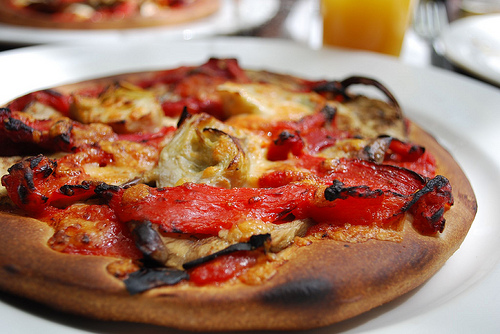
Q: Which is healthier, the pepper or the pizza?
A: The pepper is healthier than the pizza.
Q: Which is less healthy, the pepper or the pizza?
A: The pizza is less healthy than the pepper.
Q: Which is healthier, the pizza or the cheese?
A: The cheese is healthier than the pizza.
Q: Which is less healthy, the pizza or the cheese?
A: The pizza is less healthy than the cheese.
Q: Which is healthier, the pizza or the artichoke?
A: The artichoke is healthier than the pizza.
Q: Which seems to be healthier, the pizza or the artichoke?
A: The artichoke is healthier than the pizza.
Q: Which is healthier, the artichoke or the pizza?
A: The artichoke is healthier than the pizza.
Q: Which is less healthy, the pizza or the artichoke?
A: The pizza is less healthy than the artichoke.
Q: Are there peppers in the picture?
A: Yes, there is a pepper.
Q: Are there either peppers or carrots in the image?
A: Yes, there is a pepper.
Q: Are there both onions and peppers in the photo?
A: No, there is a pepper but no onions.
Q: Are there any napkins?
A: No, there are no napkins.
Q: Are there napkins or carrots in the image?
A: No, there are no napkins or carrots.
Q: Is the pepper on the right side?
A: Yes, the pepper is on the right of the image.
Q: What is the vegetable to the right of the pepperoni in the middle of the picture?
A: The vegetable is a pepper.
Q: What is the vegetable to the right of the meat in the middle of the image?
A: The vegetable is a pepper.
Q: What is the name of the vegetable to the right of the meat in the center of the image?
A: The vegetable is a pepper.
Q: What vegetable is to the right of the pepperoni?
A: The vegetable is a pepper.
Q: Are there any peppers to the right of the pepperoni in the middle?
A: Yes, there is a pepper to the right of the pepperoni.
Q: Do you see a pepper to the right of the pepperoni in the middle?
A: Yes, there is a pepper to the right of the pepperoni.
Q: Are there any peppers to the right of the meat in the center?
A: Yes, there is a pepper to the right of the pepperoni.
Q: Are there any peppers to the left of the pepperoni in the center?
A: No, the pepper is to the right of the pepperoni.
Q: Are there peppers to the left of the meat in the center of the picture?
A: No, the pepper is to the right of the pepperoni.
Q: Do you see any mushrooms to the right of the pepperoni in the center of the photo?
A: No, there is a pepper to the right of the pepperoni.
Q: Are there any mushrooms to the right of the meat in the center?
A: No, there is a pepper to the right of the pepperoni.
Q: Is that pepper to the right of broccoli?
A: No, the pepper is to the right of the pepperoni.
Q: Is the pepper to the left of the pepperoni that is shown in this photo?
A: No, the pepper is to the right of the pepperoni.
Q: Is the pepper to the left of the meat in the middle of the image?
A: No, the pepper is to the right of the pepperoni.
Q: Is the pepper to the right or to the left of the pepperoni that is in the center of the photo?
A: The pepper is to the right of the pepperoni.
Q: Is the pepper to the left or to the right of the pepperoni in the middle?
A: The pepper is to the right of the pepperoni.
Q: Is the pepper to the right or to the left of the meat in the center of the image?
A: The pepper is to the right of the pepperoni.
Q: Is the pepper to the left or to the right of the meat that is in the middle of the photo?
A: The pepper is to the right of the pepperoni.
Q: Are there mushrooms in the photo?
A: No, there are no mushrooms.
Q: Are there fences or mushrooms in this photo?
A: No, there are no mushrooms or fences.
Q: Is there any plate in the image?
A: Yes, there is a plate.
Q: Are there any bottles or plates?
A: Yes, there is a plate.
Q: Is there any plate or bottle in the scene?
A: Yes, there is a plate.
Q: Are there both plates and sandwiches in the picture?
A: No, there is a plate but no sandwiches.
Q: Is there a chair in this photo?
A: No, there are no chairs.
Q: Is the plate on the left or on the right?
A: The plate is on the right of the image.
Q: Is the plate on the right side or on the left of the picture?
A: The plate is on the right of the image.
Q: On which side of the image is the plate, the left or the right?
A: The plate is on the right of the image.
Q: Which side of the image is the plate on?
A: The plate is on the right of the image.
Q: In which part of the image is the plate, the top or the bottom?
A: The plate is in the top of the image.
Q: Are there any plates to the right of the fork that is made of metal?
A: Yes, there is a plate to the right of the fork.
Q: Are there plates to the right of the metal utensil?
A: Yes, there is a plate to the right of the fork.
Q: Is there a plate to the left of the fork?
A: No, the plate is to the right of the fork.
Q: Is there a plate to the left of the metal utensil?
A: No, the plate is to the right of the fork.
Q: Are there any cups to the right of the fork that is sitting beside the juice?
A: No, there is a plate to the right of the fork.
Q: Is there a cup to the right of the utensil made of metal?
A: No, there is a plate to the right of the fork.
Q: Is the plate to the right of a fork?
A: Yes, the plate is to the right of a fork.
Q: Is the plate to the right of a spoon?
A: No, the plate is to the right of a fork.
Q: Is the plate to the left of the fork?
A: No, the plate is to the right of the fork.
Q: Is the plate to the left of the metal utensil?
A: No, the plate is to the right of the fork.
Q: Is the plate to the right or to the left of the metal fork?
A: The plate is to the right of the fork.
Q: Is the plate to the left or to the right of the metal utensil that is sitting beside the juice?
A: The plate is to the right of the fork.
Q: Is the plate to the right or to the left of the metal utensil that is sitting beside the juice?
A: The plate is to the right of the fork.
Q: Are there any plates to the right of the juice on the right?
A: Yes, there is a plate to the right of the juice.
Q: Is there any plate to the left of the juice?
A: No, the plate is to the right of the juice.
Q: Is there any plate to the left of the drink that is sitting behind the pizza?
A: No, the plate is to the right of the juice.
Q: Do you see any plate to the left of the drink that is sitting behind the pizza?
A: No, the plate is to the right of the juice.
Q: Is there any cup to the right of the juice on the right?
A: No, there is a plate to the right of the juice.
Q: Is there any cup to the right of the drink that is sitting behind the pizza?
A: No, there is a plate to the right of the juice.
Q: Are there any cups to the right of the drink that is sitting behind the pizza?
A: No, there is a plate to the right of the juice.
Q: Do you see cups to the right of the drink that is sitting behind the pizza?
A: No, there is a plate to the right of the juice.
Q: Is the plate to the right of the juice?
A: Yes, the plate is to the right of the juice.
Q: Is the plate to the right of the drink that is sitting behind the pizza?
A: Yes, the plate is to the right of the juice.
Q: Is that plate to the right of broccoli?
A: No, the plate is to the right of the juice.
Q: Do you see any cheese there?
A: Yes, there is cheese.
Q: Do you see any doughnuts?
A: No, there are no doughnuts.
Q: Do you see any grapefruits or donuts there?
A: No, there are no donuts or grapefruits.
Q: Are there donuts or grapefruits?
A: No, there are no donuts or grapefruits.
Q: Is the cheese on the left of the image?
A: Yes, the cheese is on the left of the image.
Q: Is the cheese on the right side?
A: No, the cheese is on the left of the image.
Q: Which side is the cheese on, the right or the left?
A: The cheese is on the left of the image.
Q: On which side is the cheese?
A: The cheese is on the left of the image.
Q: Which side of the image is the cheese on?
A: The cheese is on the left of the image.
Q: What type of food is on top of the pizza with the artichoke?
A: The food is cheese.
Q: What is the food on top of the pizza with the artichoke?
A: The food is cheese.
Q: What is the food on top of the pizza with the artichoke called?
A: The food is cheese.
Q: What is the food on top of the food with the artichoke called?
A: The food is cheese.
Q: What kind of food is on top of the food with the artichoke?
A: The food is cheese.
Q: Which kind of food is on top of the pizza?
A: The food is cheese.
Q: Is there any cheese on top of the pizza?
A: Yes, there is cheese on top of the pizza.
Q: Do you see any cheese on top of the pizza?
A: Yes, there is cheese on top of the pizza.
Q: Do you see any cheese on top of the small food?
A: Yes, there is cheese on top of the pizza.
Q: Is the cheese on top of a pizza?
A: Yes, the cheese is on top of a pizza.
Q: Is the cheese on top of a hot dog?
A: No, the cheese is on top of a pizza.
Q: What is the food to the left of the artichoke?
A: The food is cheese.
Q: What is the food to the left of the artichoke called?
A: The food is cheese.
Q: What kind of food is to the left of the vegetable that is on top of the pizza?
A: The food is cheese.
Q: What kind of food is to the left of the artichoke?
A: The food is cheese.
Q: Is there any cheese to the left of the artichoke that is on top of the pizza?
A: Yes, there is cheese to the left of the artichoke.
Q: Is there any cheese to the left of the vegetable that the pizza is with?
A: Yes, there is cheese to the left of the artichoke.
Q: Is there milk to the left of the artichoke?
A: No, there is cheese to the left of the artichoke.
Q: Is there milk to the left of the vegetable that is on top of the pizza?
A: No, there is cheese to the left of the artichoke.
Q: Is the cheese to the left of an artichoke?
A: Yes, the cheese is to the left of an artichoke.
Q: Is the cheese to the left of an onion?
A: No, the cheese is to the left of an artichoke.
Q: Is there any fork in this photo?
A: Yes, there is a fork.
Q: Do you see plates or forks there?
A: Yes, there is a fork.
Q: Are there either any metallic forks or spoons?
A: Yes, there is a metal fork.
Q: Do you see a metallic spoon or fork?
A: Yes, there is a metal fork.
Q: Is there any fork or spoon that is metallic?
A: Yes, the fork is metallic.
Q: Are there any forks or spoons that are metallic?
A: Yes, the fork is metallic.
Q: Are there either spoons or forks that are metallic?
A: Yes, the fork is metallic.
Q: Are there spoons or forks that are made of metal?
A: Yes, the fork is made of metal.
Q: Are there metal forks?
A: Yes, there is a fork that is made of metal.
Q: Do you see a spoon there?
A: No, there are no spoons.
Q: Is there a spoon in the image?
A: No, there are no spoons.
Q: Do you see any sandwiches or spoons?
A: No, there are no spoons or sandwiches.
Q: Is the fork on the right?
A: Yes, the fork is on the right of the image.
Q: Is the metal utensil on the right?
A: Yes, the fork is on the right of the image.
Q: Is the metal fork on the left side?
A: No, the fork is on the right of the image.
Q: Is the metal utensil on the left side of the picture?
A: No, the fork is on the right of the image.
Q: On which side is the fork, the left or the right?
A: The fork is on the right of the image.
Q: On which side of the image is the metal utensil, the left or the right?
A: The fork is on the right of the image.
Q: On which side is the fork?
A: The fork is on the right of the image.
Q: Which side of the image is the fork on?
A: The fork is on the right of the image.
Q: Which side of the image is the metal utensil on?
A: The fork is on the right of the image.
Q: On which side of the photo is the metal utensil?
A: The fork is on the right of the image.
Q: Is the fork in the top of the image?
A: Yes, the fork is in the top of the image.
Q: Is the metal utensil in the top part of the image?
A: Yes, the fork is in the top of the image.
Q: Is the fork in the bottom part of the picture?
A: No, the fork is in the top of the image.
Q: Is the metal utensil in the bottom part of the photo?
A: No, the fork is in the top of the image.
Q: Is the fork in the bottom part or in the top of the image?
A: The fork is in the top of the image.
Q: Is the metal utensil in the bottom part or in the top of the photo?
A: The fork is in the top of the image.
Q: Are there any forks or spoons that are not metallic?
A: No, there is a fork but it is metallic.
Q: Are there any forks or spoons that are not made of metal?
A: No, there is a fork but it is made of metal.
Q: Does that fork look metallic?
A: Yes, the fork is metallic.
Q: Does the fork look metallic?
A: Yes, the fork is metallic.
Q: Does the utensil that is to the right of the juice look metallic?
A: Yes, the fork is metallic.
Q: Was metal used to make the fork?
A: Yes, the fork is made of metal.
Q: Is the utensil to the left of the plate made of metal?
A: Yes, the fork is made of metal.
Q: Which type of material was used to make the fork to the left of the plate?
A: The fork is made of metal.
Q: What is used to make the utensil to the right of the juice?
A: The fork is made of metal.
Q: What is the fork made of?
A: The fork is made of metal.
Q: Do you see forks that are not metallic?
A: No, there is a fork but it is metallic.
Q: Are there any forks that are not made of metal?
A: No, there is a fork but it is made of metal.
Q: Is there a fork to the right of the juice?
A: Yes, there is a fork to the right of the juice.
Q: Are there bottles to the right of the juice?
A: No, there is a fork to the right of the juice.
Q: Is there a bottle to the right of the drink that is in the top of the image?
A: No, there is a fork to the right of the juice.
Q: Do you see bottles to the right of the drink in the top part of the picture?
A: No, there is a fork to the right of the juice.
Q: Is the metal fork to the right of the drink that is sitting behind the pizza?
A: Yes, the fork is to the right of the juice.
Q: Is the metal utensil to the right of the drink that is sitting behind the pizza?
A: Yes, the fork is to the right of the juice.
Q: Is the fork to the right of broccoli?
A: No, the fork is to the right of the juice.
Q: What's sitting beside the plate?
A: The fork is sitting beside the plate.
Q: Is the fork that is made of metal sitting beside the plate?
A: Yes, the fork is sitting beside the plate.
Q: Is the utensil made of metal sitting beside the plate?
A: Yes, the fork is sitting beside the plate.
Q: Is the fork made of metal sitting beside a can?
A: No, the fork is sitting beside the plate.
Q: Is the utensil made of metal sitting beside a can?
A: No, the fork is sitting beside the plate.